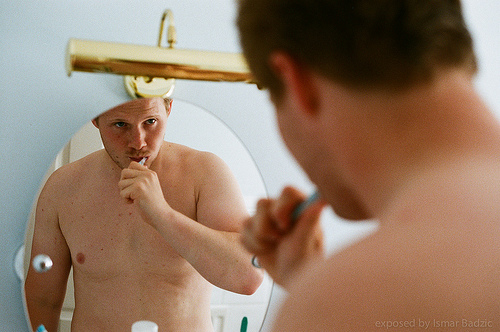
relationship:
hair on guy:
[233, 0, 484, 108] [236, 0, 500, 331]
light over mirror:
[57, 9, 249, 87] [21, 94, 278, 330]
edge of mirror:
[228, 129, 255, 154] [180, 106, 202, 138]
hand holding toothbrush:
[108, 162, 190, 219] [134, 155, 152, 166]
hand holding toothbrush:
[235, 184, 329, 295] [287, 178, 326, 220]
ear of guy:
[263, 50, 322, 122] [236, 0, 500, 331]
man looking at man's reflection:
[232, 1, 499, 326] [14, 97, 270, 330]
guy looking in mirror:
[236, 0, 500, 331] [21, 94, 278, 330]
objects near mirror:
[28, 316, 263, 330] [21, 94, 278, 330]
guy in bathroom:
[236, 1, 499, 329] [0, 0, 499, 329]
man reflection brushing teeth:
[25, 96, 264, 328] [125, 155, 148, 167]